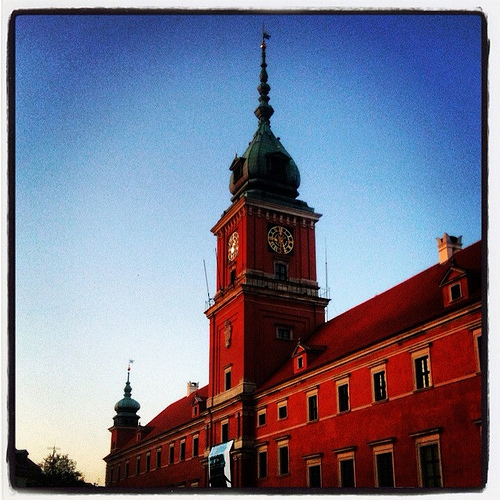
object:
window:
[308, 395, 318, 421]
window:
[338, 383, 349, 411]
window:
[374, 369, 387, 402]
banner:
[207, 440, 234, 489]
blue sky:
[14, 14, 481, 487]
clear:
[12, 17, 483, 492]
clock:
[267, 226, 294, 255]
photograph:
[0, 0, 500, 500]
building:
[102, 14, 486, 493]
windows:
[193, 438, 199, 456]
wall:
[246, 206, 318, 296]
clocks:
[227, 231, 239, 261]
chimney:
[435, 232, 463, 265]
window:
[415, 355, 431, 390]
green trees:
[37, 445, 85, 491]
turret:
[254, 18, 275, 125]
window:
[339, 458, 355, 489]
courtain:
[415, 356, 430, 389]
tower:
[203, 20, 331, 409]